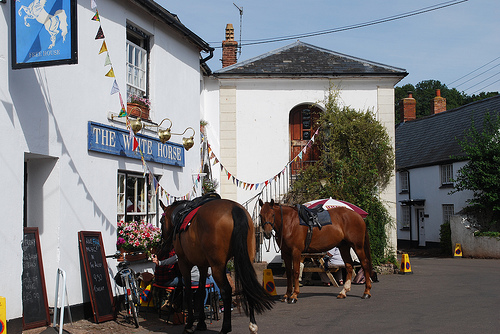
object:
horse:
[161, 192, 288, 334]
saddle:
[295, 203, 333, 226]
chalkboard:
[21, 227, 51, 328]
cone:
[398, 253, 413, 275]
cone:
[0, 297, 7, 334]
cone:
[262, 269, 279, 299]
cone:
[452, 243, 463, 258]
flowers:
[134, 240, 141, 246]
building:
[395, 89, 499, 257]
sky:
[156, 1, 498, 96]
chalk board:
[77, 230, 117, 322]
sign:
[9, 0, 79, 70]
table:
[282, 253, 339, 287]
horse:
[259, 198, 373, 303]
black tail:
[231, 206, 285, 318]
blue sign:
[87, 121, 185, 167]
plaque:
[86, 120, 183, 166]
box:
[125, 251, 147, 265]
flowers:
[118, 230, 125, 236]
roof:
[210, 39, 409, 85]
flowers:
[129, 94, 151, 107]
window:
[125, 19, 153, 121]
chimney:
[221, 23, 237, 67]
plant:
[279, 79, 399, 273]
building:
[205, 25, 409, 276]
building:
[0, 0, 213, 333]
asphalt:
[26, 239, 500, 334]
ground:
[25, 245, 499, 334]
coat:
[171, 192, 220, 240]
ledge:
[107, 112, 158, 133]